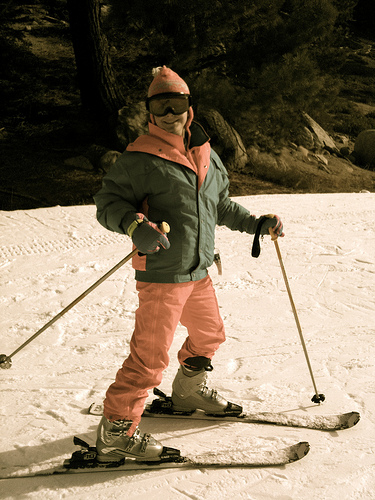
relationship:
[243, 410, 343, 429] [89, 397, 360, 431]
snow covering ski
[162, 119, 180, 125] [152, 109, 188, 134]
smile on face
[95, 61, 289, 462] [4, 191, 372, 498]
skier standing on snow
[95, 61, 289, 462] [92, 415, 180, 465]
skier wearing ski boot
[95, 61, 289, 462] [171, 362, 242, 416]
skier wearing ski boot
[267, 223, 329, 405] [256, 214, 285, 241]
ski pole in hand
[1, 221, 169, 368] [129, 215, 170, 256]
ski pole in hand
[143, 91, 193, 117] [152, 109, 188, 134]
goggles are on face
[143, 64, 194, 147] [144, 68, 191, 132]
hat on head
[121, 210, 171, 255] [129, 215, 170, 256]
glove on hand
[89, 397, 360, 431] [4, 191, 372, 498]
ski on snow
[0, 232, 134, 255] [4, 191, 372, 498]
tracks are on snow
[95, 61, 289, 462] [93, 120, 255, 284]
skier wearing jacket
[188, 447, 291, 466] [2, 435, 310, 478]
snow on ski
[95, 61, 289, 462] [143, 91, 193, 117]
skier wearing goggles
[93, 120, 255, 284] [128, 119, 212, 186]
jacket has trim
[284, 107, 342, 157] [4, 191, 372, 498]
boulder near snow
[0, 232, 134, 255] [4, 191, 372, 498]
tracks are in snow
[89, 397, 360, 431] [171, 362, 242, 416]
ski attached to ski boot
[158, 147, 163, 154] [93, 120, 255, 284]
button on jacket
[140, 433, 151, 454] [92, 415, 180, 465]
clasp on ski boot